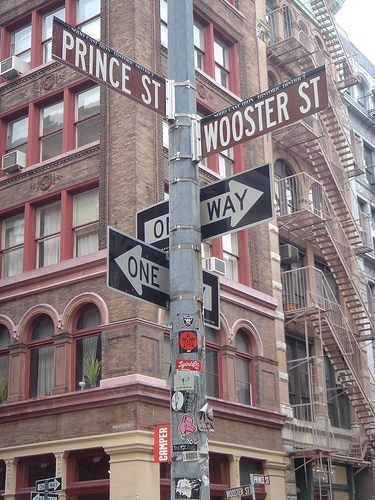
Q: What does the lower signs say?
A: One way.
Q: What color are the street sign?
A: Brown.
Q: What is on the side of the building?
A: Fire escape.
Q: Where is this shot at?
A: Intersection.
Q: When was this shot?
A: Daytime.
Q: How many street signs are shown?
A: 2.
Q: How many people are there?
A: 0.